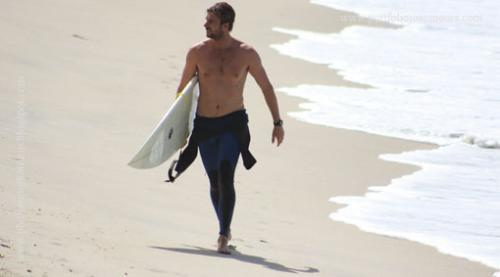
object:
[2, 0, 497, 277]
beach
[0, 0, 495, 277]
sand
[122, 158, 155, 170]
tip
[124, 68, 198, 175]
surfboard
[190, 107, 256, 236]
wetsuit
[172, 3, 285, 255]
man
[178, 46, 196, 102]
arm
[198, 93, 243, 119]
stomach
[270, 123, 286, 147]
hand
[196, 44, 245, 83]
chest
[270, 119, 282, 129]
watch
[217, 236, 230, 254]
feet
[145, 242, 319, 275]
shadow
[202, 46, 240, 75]
hair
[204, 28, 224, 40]
beard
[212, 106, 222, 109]
belly-button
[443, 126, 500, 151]
waves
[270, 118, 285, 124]
wrist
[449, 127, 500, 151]
foam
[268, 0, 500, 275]
water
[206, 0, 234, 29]
hair